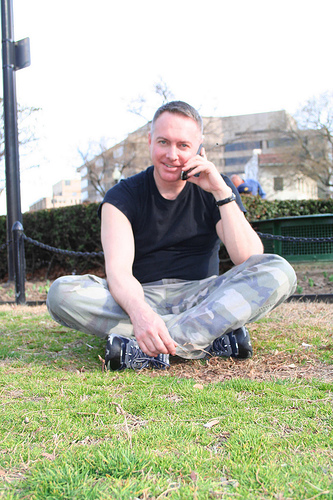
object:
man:
[46, 100, 298, 371]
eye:
[178, 143, 188, 149]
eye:
[158, 138, 170, 147]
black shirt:
[98, 163, 248, 282]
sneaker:
[209, 324, 252, 360]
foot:
[206, 325, 252, 357]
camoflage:
[170, 284, 232, 330]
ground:
[211, 113, 255, 164]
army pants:
[46, 254, 297, 359]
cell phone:
[181, 144, 202, 181]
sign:
[14, 36, 31, 71]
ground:
[261, 125, 303, 197]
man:
[230, 173, 265, 198]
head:
[231, 174, 244, 188]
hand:
[133, 310, 178, 358]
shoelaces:
[123, 347, 169, 370]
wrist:
[128, 302, 152, 323]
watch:
[215, 193, 236, 206]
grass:
[0, 303, 332, 500]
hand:
[182, 147, 225, 194]